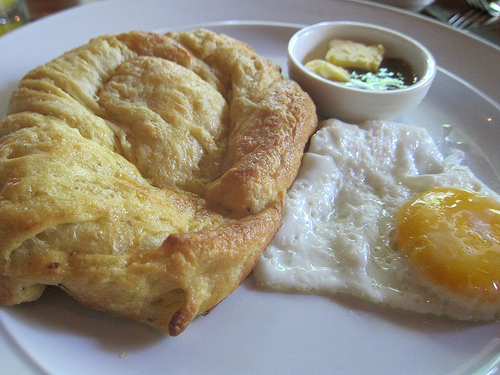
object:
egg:
[252, 116, 500, 324]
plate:
[1, 2, 500, 370]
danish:
[5, 29, 319, 336]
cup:
[288, 21, 436, 124]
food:
[7, 20, 496, 335]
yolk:
[389, 188, 500, 304]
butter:
[324, 35, 384, 72]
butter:
[301, 58, 354, 85]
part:
[168, 290, 199, 337]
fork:
[446, 2, 496, 34]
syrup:
[342, 54, 418, 92]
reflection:
[487, 114, 491, 125]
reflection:
[464, 342, 496, 369]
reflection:
[214, 20, 304, 30]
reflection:
[347, 66, 417, 90]